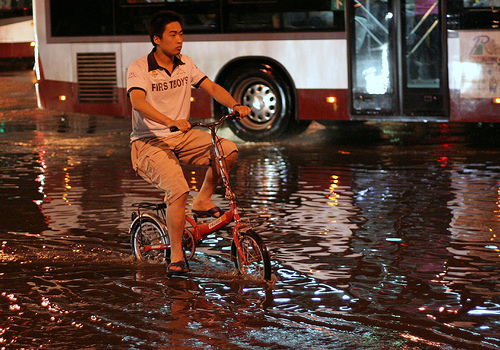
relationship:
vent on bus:
[78, 41, 128, 113] [29, 0, 498, 142]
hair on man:
[149, 18, 180, 45] [123, 10, 251, 275]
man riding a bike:
[129, 15, 246, 272] [127, 109, 271, 281]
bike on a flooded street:
[127, 109, 271, 281] [2, 114, 498, 346]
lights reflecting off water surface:
[294, 170, 354, 247] [3, 146, 498, 348]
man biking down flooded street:
[129, 15, 246, 272] [0, 69, 499, 349]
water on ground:
[0, 115, 493, 346] [95, 200, 261, 265]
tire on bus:
[223, 67, 295, 151] [29, 0, 498, 142]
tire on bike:
[126, 216, 186, 269] [128, 187, 281, 274]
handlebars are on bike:
[167, 110, 237, 134] [128, 118, 284, 292]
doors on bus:
[347, 2, 452, 120] [29, 0, 498, 142]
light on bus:
[60, 95, 65, 109] [29, 0, 498, 142]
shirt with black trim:
[125, 45, 210, 145] [193, 75, 208, 88]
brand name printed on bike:
[200, 210, 224, 240] [97, 188, 306, 296]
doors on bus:
[347, 0, 405, 122] [29, 0, 498, 142]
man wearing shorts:
[129, 15, 246, 272] [130, 127, 238, 207]